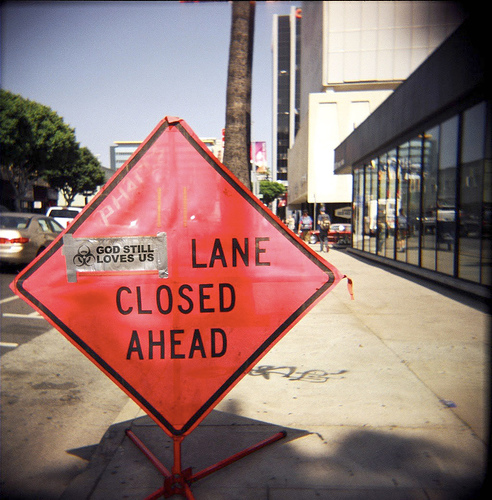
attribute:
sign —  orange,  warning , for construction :
[16, 115, 337, 434]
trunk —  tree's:
[226, 3, 261, 193]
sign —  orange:
[4, 114, 359, 498]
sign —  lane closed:
[75, 128, 316, 391]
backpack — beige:
[318, 211, 333, 231]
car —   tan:
[4, 205, 99, 285]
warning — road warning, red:
[9, 145, 354, 482]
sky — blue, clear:
[0, 2, 279, 172]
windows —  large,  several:
[350, 163, 454, 250]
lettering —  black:
[114, 223, 270, 364]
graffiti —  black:
[96, 162, 148, 223]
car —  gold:
[0, 209, 67, 270]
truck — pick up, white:
[23, 200, 78, 233]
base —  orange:
[123, 427, 286, 497]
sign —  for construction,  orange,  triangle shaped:
[8, 112, 374, 438]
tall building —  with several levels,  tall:
[250, 14, 344, 215]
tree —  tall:
[223, 3, 256, 194]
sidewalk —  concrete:
[78, 229, 489, 497]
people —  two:
[295, 203, 332, 253]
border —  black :
[230, 358, 247, 378]